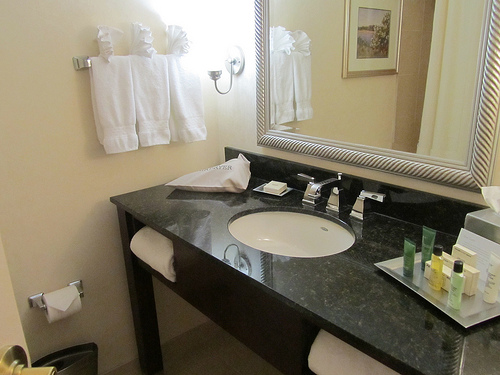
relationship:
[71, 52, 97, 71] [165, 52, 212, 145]
towel rack with towel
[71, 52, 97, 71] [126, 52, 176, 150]
towel rack with towel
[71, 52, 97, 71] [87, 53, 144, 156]
towel rack with towel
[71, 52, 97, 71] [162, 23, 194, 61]
towel rack with towel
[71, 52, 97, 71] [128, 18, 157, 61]
towel rack with towel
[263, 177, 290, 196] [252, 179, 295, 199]
soap in dish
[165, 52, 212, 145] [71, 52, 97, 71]
towel hanging on towel rack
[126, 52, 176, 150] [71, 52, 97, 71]
towel hanging on towel rack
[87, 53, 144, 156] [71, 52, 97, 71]
towel hanging on towel rack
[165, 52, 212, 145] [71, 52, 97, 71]
towel arranged on towel rack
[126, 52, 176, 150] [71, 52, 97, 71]
towel arranged on towel rack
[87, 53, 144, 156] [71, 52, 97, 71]
towel arranged on towel rack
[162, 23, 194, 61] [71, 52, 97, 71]
towel arranged on towel rack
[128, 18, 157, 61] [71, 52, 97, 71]
towel arranged on towel rack